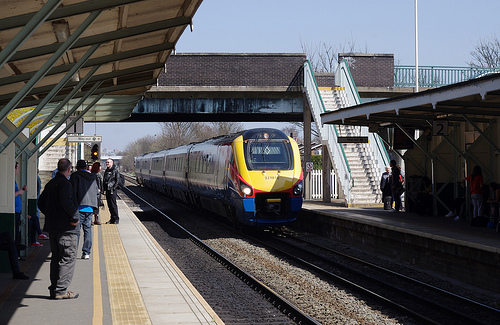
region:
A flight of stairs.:
[300, 47, 395, 213]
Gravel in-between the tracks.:
[250, 238, 351, 319]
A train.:
[130, 105, 310, 230]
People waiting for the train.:
[5, 135, 132, 310]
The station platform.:
[0, 0, 229, 322]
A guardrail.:
[390, 57, 450, 87]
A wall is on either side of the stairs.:
[160, 46, 393, 99]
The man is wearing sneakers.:
[40, 275, 80, 310]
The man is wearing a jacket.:
[65, 155, 95, 210]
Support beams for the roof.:
[5, 0, 126, 150]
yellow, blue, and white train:
[133, 125, 304, 229]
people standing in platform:
[36, 156, 122, 303]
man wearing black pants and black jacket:
[99, 157, 122, 229]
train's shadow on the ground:
[120, 182, 245, 241]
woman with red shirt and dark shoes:
[461, 164, 488, 226]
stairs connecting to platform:
[301, 57, 399, 212]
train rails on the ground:
[115, 171, 499, 323]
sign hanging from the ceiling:
[335, 120, 373, 147]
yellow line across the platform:
[90, 197, 149, 324]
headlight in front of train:
[241, 183, 306, 196]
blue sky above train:
[226, 8, 287, 36]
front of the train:
[229, 120, 311, 227]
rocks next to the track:
[281, 261, 304, 281]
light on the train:
[226, 171, 264, 218]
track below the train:
[306, 245, 355, 294]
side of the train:
[161, 154, 213, 184]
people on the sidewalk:
[40, 133, 135, 240]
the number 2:
[421, 112, 461, 150]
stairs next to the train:
[323, 71, 380, 212]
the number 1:
[53, 103, 85, 145]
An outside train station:
[0, 12, 497, 323]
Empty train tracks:
[162, 222, 359, 322]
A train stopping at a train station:
[128, 115, 335, 250]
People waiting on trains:
[9, 131, 498, 300]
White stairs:
[305, 64, 402, 209]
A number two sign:
[422, 113, 460, 148]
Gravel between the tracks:
[146, 182, 403, 323]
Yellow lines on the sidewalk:
[92, 222, 180, 324]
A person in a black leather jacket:
[96, 154, 129, 235]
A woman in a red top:
[463, 163, 498, 227]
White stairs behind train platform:
[301, 50, 407, 211]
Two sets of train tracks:
[168, 221, 435, 323]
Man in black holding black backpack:
[99, 156, 130, 226]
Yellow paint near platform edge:
[87, 271, 163, 323]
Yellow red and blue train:
[229, 130, 306, 227]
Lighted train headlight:
[226, 179, 261, 207]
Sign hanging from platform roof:
[331, 115, 371, 149]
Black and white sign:
[60, 107, 89, 142]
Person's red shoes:
[33, 223, 50, 255]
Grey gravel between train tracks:
[218, 230, 323, 303]